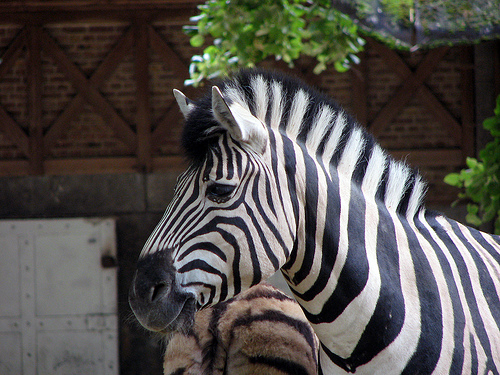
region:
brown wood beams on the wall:
[112, 13, 162, 165]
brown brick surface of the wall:
[66, 130, 116, 157]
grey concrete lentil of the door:
[2, 173, 154, 218]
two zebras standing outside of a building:
[101, 76, 499, 373]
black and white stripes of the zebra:
[361, 235, 493, 370]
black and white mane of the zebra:
[258, 68, 431, 210]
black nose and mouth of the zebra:
[128, 251, 210, 341]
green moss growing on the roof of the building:
[391, 0, 492, 47]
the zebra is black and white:
[146, 85, 498, 369]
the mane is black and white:
[317, 129, 432, 209]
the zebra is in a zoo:
[138, 71, 493, 369]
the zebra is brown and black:
[176, 311, 323, 373]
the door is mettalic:
[17, 222, 126, 374]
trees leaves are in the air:
[208, 7, 362, 78]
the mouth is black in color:
[148, 278, 203, 327]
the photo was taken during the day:
[8, 5, 498, 372]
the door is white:
[10, 218, 130, 370]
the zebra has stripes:
[109, 79, 433, 374]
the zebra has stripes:
[104, 69, 484, 372]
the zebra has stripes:
[115, 75, 433, 374]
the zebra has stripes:
[115, 56, 415, 368]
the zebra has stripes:
[125, 78, 409, 358]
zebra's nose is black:
[98, 238, 219, 350]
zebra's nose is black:
[100, 230, 232, 365]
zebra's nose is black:
[95, 233, 225, 353]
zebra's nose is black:
[113, 238, 228, 358]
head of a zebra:
[118, 65, 303, 335]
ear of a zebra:
[156, 77, 273, 153]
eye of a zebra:
[202, 171, 242, 203]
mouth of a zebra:
[125, 241, 211, 352]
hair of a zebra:
[227, 70, 440, 218]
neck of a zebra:
[273, 185, 409, 370]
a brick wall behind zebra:
[25, 20, 163, 155]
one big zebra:
[121, 64, 497, 368]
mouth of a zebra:
[128, 295, 198, 335]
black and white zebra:
[91, 63, 497, 373]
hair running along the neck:
[173, 62, 432, 224]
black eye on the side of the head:
[205, 176, 242, 209]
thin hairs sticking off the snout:
[114, 294, 205, 351]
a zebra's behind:
[133, 268, 325, 373]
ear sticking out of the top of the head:
[202, 84, 260, 151]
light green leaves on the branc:
[169, 6, 364, 87]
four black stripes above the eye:
[197, 138, 250, 189]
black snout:
[115, 241, 210, 344]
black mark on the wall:
[94, 246, 121, 273]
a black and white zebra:
[105, 39, 499, 363]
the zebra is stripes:
[112, 60, 494, 373]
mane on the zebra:
[173, 59, 455, 213]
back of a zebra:
[129, 283, 311, 373]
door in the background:
[16, 197, 125, 368]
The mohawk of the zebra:
[181, 67, 425, 215]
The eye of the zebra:
[207, 182, 237, 198]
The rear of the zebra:
[164, 280, 320, 374]